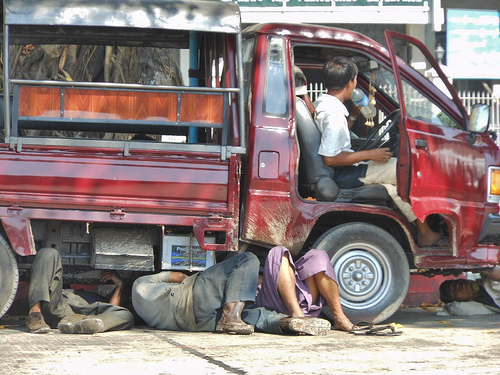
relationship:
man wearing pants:
[259, 244, 364, 333] [251, 245, 338, 318]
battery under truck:
[161, 234, 217, 273] [0, 0, 499, 327]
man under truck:
[439, 268, 499, 316] [0, 0, 499, 327]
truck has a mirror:
[0, 0, 499, 327] [466, 103, 490, 134]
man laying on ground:
[439, 268, 499, 316] [0, 307, 499, 374]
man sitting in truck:
[313, 55, 452, 247] [0, 0, 499, 327]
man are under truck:
[24, 247, 135, 333] [0, 0, 499, 327]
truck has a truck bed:
[0, 0, 499, 327] [0, 2, 242, 256]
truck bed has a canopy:
[0, 2, 242, 256] [0, 0, 246, 161]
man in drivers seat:
[313, 55, 452, 247] [293, 97, 390, 202]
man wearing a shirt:
[131, 252, 332, 336] [132, 271, 208, 331]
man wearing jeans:
[131, 252, 332, 336] [193, 251, 290, 335]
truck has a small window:
[0, 0, 499, 327] [264, 33, 289, 118]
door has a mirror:
[384, 29, 487, 257] [466, 103, 490, 134]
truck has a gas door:
[0, 0, 499, 327] [259, 151, 280, 179]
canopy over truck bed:
[0, 0, 246, 161] [0, 2, 242, 256]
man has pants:
[313, 55, 452, 247] [353, 158, 418, 222]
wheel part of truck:
[309, 222, 410, 330] [0, 0, 499, 327]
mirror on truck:
[466, 103, 490, 134] [0, 0, 499, 327]